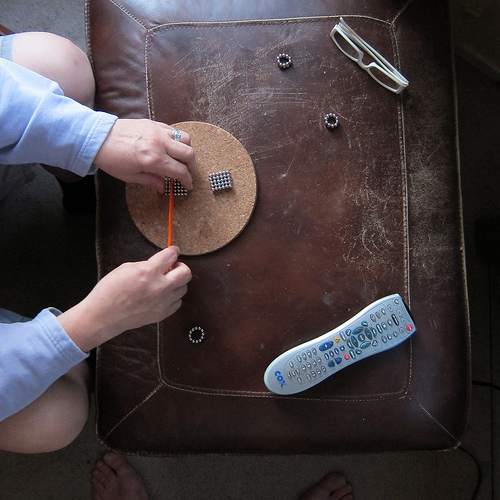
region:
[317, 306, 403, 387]
This is a remote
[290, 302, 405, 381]
the remote is grey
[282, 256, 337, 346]
these are some buttons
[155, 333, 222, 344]
this is a ring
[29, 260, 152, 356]
this is a man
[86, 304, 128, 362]
this is a wrist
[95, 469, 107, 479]
this is a foot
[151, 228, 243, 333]
these are some fingers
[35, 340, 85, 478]
this is a knee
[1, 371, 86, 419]
this is a blue sweatshirt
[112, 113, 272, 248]
a board on teh ottoman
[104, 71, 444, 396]
a brown ottoman inside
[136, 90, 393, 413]
a brown leather ottoman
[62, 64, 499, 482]
a worn brown ottoman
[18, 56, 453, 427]
a worn leather ottoman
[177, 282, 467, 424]
a remote on the ottoman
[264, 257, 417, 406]
a remote on a leather remote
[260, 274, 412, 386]
a remote on a brown ottoman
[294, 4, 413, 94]
glass on an ottoman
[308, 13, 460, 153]
glasses on a brown ottoman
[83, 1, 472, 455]
Brown leather ottoman on floor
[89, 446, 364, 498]
Feet standing on carpet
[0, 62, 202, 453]
Person holding an orange object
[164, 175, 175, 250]
Orange cutting device of some sort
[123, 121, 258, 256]
Circular cork cutting board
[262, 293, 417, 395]
Silver remote control on ottoman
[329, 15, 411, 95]
Pair of white rimmed glasses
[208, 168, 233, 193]
Black and white square object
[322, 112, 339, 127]
Circle shaped object on ottoman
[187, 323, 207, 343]
Circle shaped object on ottoman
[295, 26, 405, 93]
sunglasses on the table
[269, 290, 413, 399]
remote on the table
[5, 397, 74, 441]
knee of the person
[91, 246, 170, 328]
hand of the person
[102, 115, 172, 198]
hand of the person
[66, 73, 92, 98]
knee of the person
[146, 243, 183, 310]
fingers of the person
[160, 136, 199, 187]
fingers of the person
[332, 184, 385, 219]
the table is old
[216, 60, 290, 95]
the table is wood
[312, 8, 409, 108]
glasses on the table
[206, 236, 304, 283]
the table is brown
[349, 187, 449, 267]
the table is old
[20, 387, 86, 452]
knee of the person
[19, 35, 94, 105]
knee of the person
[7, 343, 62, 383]
the sleeve is blue